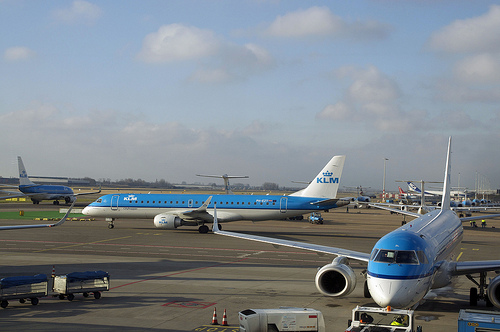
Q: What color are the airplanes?
A: Blue and White.